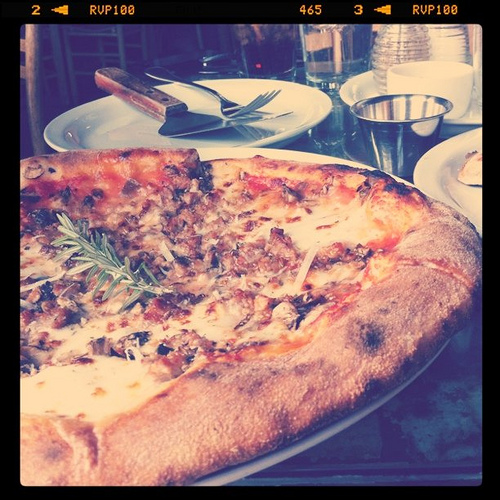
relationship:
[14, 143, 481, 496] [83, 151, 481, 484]
pizza on plate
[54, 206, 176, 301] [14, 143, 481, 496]
green leaf on pizza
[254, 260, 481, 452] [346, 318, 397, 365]
crust has burn mark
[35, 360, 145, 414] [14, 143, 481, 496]
cheese on pizza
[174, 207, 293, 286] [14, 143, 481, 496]
sausage on pizza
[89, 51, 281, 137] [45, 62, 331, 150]
utensils on white plate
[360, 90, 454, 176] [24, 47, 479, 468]
bowl on table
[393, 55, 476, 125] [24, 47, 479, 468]
white bowl on table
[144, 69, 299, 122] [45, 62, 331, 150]
fork on white plate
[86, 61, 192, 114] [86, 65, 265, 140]
handle on spatula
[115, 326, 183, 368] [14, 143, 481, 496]
black olives on pizza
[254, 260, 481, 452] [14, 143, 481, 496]
crust on pizza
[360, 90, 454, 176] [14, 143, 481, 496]
bowl beside pizza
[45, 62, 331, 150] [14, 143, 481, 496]
white plate near pizza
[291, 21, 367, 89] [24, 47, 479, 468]
glass cup on table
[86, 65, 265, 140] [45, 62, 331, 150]
spatula on white plate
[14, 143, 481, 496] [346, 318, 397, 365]
pizza has burn mark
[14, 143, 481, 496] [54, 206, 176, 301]
pizza with green leaf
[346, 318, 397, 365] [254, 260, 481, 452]
burn mark on crust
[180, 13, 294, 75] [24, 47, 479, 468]
condiments on table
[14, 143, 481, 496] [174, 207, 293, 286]
pizza has sausage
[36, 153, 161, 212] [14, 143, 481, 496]
sauce on pizza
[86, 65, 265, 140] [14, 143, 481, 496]
spatula for pizza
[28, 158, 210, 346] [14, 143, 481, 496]
toppings on pizza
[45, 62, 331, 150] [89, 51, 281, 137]
white plate has utensils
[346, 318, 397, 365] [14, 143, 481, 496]
burn mark on pizza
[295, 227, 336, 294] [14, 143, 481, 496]
onion on pizza